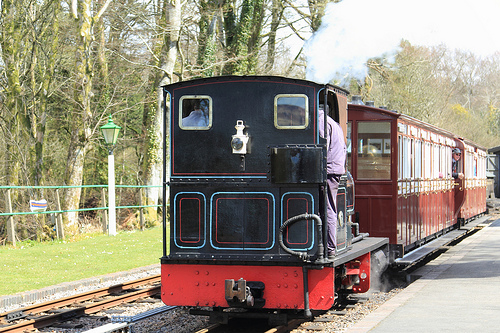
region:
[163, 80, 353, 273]
this is a train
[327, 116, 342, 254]
this is a man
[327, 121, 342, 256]
the man is standing in the door of the train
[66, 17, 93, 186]
this is a tree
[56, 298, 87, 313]
this is a railway line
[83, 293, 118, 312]
the rail is made of metal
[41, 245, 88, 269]
this is a grass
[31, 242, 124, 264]
the grass is green in color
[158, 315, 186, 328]
these are small rocks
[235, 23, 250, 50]
the tree has green leaves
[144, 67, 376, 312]
train is black and red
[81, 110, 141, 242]
pole has a green top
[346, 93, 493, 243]
train car is red and long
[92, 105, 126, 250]
Lamp post in background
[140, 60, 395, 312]
Black train engine pushing train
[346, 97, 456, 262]
Nearest red train car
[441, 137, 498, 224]
Farthest red train car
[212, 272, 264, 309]
Train car hitch on back of engine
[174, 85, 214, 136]
Left window in train engine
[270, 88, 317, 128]
Right window in train engine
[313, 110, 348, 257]
The back of the engineer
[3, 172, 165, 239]
Green metal fence in background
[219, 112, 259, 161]
Wall mounted conductors handlight on engine.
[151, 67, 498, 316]
black and red train with three cars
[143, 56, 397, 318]
black and red caboose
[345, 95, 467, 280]
Person leaning out of a red train car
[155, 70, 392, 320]
person standing in a black and red caboose.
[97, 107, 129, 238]
green lamp on a white post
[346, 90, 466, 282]
red train car with many windows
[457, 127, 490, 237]
red train car with many windows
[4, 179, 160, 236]
green metal fence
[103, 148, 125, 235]
gray stone lamp post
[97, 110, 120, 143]
green lantern on post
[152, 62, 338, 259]
black front of train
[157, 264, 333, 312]
red bottom of train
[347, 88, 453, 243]
red train car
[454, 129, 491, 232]
red train car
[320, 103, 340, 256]
conductor on side of train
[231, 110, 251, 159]
white light on train